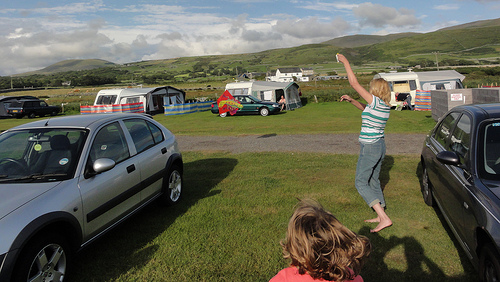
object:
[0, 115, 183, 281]
car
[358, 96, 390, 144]
shirt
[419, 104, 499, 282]
car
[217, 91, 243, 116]
kite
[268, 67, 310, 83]
house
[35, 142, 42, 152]
item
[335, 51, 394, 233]
woman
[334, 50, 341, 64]
object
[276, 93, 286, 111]
person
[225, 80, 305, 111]
tent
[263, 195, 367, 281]
female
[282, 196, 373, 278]
shiny hair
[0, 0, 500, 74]
sky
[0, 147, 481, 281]
grass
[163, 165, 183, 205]
tire